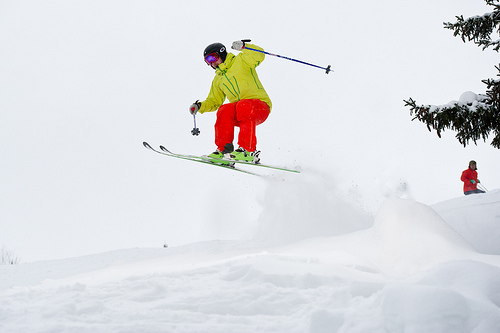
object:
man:
[142, 39, 331, 181]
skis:
[142, 141, 263, 181]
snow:
[406, 1, 499, 149]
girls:
[187, 41, 271, 165]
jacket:
[190, 41, 273, 114]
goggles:
[204, 52, 219, 64]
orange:
[213, 98, 271, 160]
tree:
[405, 0, 500, 148]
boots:
[224, 148, 263, 165]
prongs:
[190, 127, 201, 136]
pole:
[233, 37, 335, 79]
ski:
[159, 141, 302, 176]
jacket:
[460, 168, 480, 193]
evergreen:
[405, 0, 500, 155]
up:
[252, 166, 391, 238]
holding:
[229, 40, 247, 52]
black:
[202, 42, 230, 69]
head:
[201, 42, 230, 70]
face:
[204, 51, 226, 68]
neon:
[202, 148, 234, 167]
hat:
[468, 160, 479, 171]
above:
[0, 0, 499, 191]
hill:
[0, 183, 499, 331]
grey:
[0, 0, 499, 190]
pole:
[189, 104, 201, 136]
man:
[457, 159, 487, 198]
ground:
[0, 193, 499, 333]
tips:
[401, 95, 423, 115]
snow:
[1, 184, 497, 331]